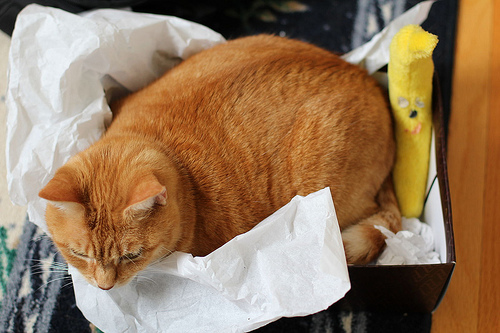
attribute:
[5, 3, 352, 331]
paper — white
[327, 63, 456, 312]
box — shoe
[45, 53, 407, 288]
cat — orange